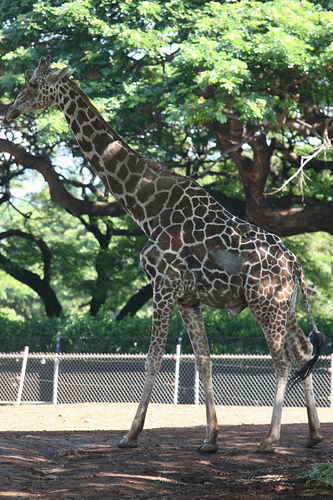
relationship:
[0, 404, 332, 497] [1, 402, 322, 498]
dirt on ground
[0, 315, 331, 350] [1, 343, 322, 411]
bushes behind fence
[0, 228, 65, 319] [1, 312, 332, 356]
tree behind bushes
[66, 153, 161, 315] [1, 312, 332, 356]
tree behind bushes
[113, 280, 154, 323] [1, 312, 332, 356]
tree behind bushes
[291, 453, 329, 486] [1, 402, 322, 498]
patch on ground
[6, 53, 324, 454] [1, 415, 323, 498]
giraffe standing in shade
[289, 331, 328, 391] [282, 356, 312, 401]
tail has hair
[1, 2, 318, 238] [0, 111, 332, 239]
tree has branch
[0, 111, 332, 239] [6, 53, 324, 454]
branch next to giraffe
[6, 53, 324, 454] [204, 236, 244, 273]
giraffe has gray spot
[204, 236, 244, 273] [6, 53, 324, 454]
gray spot on giraffe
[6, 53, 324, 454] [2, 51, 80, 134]
giraffe has head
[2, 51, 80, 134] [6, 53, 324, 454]
head on giraffe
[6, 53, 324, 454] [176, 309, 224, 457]
giraffe has leg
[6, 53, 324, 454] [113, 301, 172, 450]
giraffe has leg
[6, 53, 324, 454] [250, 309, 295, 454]
giraffe has leg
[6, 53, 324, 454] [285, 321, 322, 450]
giraffe has leg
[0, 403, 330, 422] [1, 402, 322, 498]
gravel on ground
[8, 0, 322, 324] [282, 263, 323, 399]
giraffe has tail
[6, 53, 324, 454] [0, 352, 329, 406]
giraffe walking in enclosure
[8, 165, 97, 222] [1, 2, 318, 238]
sunshine through tree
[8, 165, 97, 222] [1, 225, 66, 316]
sunshine through tree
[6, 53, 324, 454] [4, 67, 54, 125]
giraffe has face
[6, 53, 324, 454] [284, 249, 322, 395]
giraffe has tail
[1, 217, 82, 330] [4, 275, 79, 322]
tree has trunk